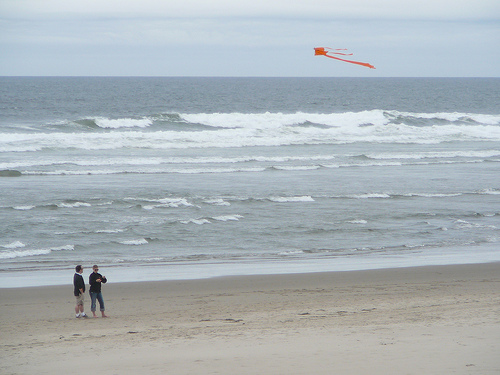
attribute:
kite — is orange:
[314, 46, 376, 70]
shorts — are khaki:
[77, 293, 95, 310]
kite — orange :
[282, 33, 403, 86]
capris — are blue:
[88, 289, 109, 315]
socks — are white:
[71, 307, 89, 314]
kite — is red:
[303, 45, 400, 97]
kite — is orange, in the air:
[308, 43, 378, 73]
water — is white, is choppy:
[60, 112, 475, 226]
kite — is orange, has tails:
[313, 45, 377, 75]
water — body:
[175, 201, 273, 257]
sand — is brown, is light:
[0, 258, 492, 373]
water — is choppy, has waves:
[153, 129, 402, 266]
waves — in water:
[232, 194, 361, 227]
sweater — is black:
[87, 270, 107, 292]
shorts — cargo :
[74, 291, 85, 308]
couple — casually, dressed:
[71, 263, 108, 320]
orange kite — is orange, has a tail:
[296, 32, 398, 85]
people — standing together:
[63, 259, 117, 323]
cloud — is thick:
[3, 0, 499, 45]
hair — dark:
[70, 261, 90, 279]